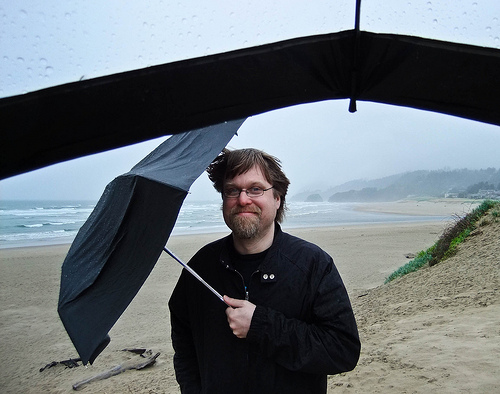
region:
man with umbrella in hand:
[49, 113, 379, 386]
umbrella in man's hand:
[51, 113, 243, 361]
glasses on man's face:
[217, 176, 281, 199]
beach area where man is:
[3, 165, 488, 385]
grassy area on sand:
[377, 200, 497, 280]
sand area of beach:
[4, 237, 489, 388]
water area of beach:
[0, 195, 417, 236]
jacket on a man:
[176, 234, 356, 392]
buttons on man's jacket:
[256, 268, 280, 286]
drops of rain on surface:
[6, 35, 64, 82]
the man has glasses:
[160, 166, 375, 392]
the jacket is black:
[173, 235, 366, 390]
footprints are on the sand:
[392, 284, 454, 371]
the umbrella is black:
[73, 191, 165, 329]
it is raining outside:
[1, 86, 491, 393]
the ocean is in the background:
[18, 195, 86, 259]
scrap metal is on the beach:
[106, 330, 163, 386]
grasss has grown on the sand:
[395, 205, 495, 275]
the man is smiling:
[187, 147, 359, 392]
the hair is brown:
[208, 140, 298, 200]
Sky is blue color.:
[16, 16, 126, 62]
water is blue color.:
[6, 201, 73, 243]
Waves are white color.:
[5, 201, 79, 236]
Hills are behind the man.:
[320, 155, 499, 220]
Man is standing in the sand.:
[155, 148, 365, 393]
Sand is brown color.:
[383, 307, 483, 390]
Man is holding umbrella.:
[56, 174, 363, 379]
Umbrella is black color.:
[46, 163, 203, 355]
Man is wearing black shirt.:
[166, 230, 358, 376]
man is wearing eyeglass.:
[202, 161, 306, 266]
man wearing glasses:
[221, 179, 281, 234]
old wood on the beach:
[39, 358, 147, 391]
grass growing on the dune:
[399, 196, 491, 284]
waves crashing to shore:
[14, 200, 56, 237]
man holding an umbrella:
[59, 153, 305, 335]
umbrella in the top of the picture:
[17, 17, 497, 162]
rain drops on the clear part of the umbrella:
[0, 13, 108, 75]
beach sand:
[382, 292, 467, 370]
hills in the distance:
[317, 163, 472, 205]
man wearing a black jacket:
[182, 248, 344, 390]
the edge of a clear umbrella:
[0, 5, 491, 158]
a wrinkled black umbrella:
[51, 125, 264, 367]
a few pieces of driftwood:
[38, 345, 163, 387]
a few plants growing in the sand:
[390, 200, 490, 275]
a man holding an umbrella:
[53, 112, 374, 387]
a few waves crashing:
[3, 189, 102, 246]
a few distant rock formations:
[299, 182, 387, 206]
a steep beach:
[383, 197, 461, 222]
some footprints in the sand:
[366, 317, 439, 387]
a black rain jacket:
[166, 228, 365, 389]